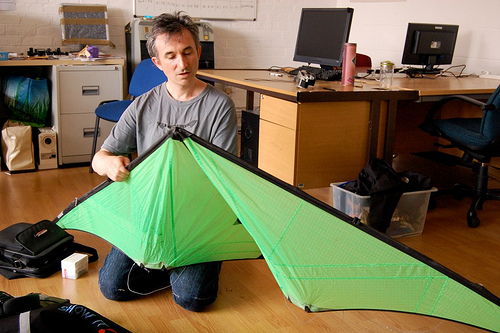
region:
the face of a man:
[130, 10, 215, 90]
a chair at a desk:
[426, 67, 496, 187]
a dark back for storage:
[7, 215, 98, 285]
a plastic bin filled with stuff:
[327, 165, 433, 245]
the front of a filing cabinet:
[45, 55, 145, 166]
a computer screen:
[295, 10, 356, 67]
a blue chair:
[85, 50, 170, 130]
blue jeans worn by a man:
[98, 239, 220, 314]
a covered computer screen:
[57, 4, 115, 48]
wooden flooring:
[8, 180, 57, 213]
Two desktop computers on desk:
[268, 5, 490, 104]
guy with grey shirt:
[100, 20, 242, 138]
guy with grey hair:
[113, 6, 252, 141]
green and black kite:
[48, 117, 468, 331]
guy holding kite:
[70, 17, 423, 331]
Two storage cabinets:
[41, 48, 129, 168]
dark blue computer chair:
[429, 63, 499, 230]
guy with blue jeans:
[73, 15, 254, 327]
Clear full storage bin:
[320, 160, 462, 245]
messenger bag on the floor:
[3, 201, 98, 291]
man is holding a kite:
[129, 139, 377, 329]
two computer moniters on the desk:
[273, 4, 465, 81]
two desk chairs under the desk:
[341, 25, 498, 161]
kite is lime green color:
[104, 118, 474, 328]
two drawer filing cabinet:
[45, 50, 145, 162]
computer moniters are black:
[288, 16, 474, 88]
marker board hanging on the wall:
[125, 0, 272, 28]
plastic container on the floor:
[292, 158, 479, 249]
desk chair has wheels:
[420, 103, 486, 261]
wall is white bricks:
[223, 26, 294, 66]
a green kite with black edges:
[55, 126, 498, 331]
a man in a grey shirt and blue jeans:
[90, 12, 237, 310]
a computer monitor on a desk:
[400, 20, 460, 75]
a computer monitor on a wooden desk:
[293, 6, 354, 78]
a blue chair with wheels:
[419, 82, 496, 228]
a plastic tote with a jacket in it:
[328, 156, 438, 237]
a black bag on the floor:
[0, 216, 99, 279]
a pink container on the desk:
[341, 41, 357, 86]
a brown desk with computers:
[196, 67, 498, 191]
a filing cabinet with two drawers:
[51, 65, 124, 165]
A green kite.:
[54, 125, 497, 329]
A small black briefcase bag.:
[0, 217, 92, 279]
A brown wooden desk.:
[189, 60, 499, 195]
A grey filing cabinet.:
[49, 67, 124, 164]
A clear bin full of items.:
[331, 180, 437, 237]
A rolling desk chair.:
[432, 82, 498, 234]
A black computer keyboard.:
[287, 65, 345, 82]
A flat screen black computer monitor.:
[289, 8, 353, 64]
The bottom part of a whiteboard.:
[131, 0, 258, 21]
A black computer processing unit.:
[239, 109, 261, 171]